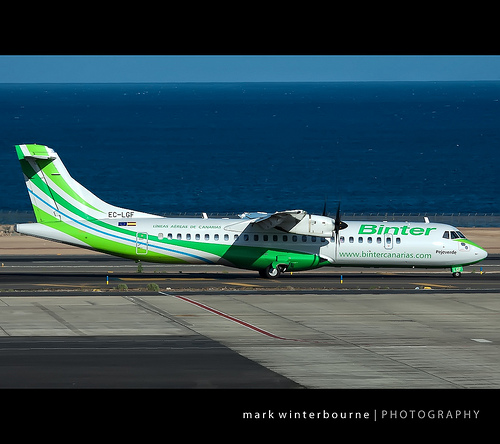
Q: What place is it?
A: It is a runway.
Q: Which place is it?
A: It is a runway.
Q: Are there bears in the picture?
A: No, there are no bears.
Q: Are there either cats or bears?
A: No, there are no bears or cats.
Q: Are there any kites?
A: No, there are no kites.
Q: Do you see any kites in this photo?
A: No, there are no kites.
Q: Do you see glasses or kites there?
A: No, there are no kites or glasses.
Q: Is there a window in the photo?
A: Yes, there are windows.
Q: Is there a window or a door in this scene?
A: Yes, there are windows.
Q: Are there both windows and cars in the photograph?
A: No, there are windows but no cars.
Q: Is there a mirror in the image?
A: No, there are no mirrors.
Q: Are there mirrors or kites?
A: No, there are no mirrors or kites.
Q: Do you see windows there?
A: Yes, there are windows.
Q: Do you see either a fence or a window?
A: Yes, there are windows.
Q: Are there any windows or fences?
A: Yes, there are windows.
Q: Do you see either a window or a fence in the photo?
A: Yes, there are windows.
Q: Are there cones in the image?
A: No, there are no cones.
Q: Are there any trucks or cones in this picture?
A: No, there are no cones or trucks.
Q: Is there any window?
A: Yes, there are windows.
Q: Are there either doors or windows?
A: Yes, there are windows.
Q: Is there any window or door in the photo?
A: Yes, there are windows.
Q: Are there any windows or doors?
A: Yes, there are windows.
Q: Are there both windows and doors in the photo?
A: Yes, there are both windows and a door.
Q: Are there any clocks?
A: No, there are no clocks.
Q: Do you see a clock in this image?
A: No, there are no clocks.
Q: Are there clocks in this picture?
A: No, there are no clocks.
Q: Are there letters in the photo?
A: Yes, there are letters.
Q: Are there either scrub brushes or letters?
A: Yes, there are letters.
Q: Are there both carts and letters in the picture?
A: No, there are letters but no carts.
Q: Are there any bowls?
A: No, there are no bowls.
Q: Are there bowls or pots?
A: No, there are no bowls or pots.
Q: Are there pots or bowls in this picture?
A: No, there are no bowls or pots.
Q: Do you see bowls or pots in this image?
A: No, there are no bowls or pots.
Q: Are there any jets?
A: No, there are no jets.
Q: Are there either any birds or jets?
A: No, there are no jets or birds.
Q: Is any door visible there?
A: Yes, there is a door.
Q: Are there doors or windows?
A: Yes, there is a door.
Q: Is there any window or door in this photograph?
A: Yes, there is a door.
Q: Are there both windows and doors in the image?
A: Yes, there are both a door and a window.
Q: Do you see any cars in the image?
A: No, there are no cars.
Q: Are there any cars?
A: No, there are no cars.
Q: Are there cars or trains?
A: No, there are no cars or trains.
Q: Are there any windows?
A: Yes, there are windows.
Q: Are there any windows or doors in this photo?
A: Yes, there are windows.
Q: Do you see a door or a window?
A: Yes, there are windows.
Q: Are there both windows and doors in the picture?
A: Yes, there are both windows and a door.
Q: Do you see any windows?
A: Yes, there are windows.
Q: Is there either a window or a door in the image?
A: Yes, there are windows.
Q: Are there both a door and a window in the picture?
A: Yes, there are both a window and a door.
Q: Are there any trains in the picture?
A: No, there are no trains.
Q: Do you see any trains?
A: No, there are no trains.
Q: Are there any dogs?
A: No, there are no dogs.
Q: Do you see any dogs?
A: No, there are no dogs.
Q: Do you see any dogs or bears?
A: No, there are no dogs or bears.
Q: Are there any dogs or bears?
A: No, there are no dogs or bears.